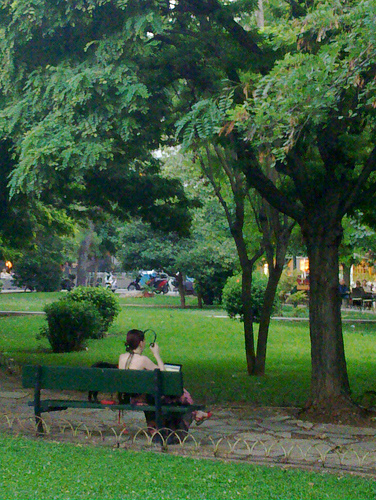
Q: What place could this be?
A: It is a park.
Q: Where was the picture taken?
A: It was taken at the park.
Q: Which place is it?
A: It is a park.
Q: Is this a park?
A: Yes, it is a park.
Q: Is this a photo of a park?
A: Yes, it is showing a park.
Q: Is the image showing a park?
A: Yes, it is showing a park.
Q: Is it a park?
A: Yes, it is a park.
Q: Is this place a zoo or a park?
A: It is a park.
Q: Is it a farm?
A: No, it is a park.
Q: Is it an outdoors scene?
A: Yes, it is outdoors.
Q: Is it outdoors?
A: Yes, it is outdoors.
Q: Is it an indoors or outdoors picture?
A: It is outdoors.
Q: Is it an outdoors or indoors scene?
A: It is outdoors.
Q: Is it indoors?
A: No, it is outdoors.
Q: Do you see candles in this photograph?
A: No, there are no candles.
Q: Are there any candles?
A: No, there are no candles.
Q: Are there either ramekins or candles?
A: No, there are no candles or ramekins.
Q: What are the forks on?
A: The forks are on the tree.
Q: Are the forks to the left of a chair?
A: Yes, the forks are to the left of a chair.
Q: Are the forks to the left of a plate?
A: No, the forks are to the left of a chair.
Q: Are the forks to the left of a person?
A: Yes, the forks are to the left of a person.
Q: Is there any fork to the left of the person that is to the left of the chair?
A: Yes, there are forks to the left of the person.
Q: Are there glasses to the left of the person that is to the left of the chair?
A: No, there are forks to the left of the person.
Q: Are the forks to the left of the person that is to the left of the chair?
A: Yes, the forks are to the left of the person.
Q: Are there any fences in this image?
A: Yes, there is a fence.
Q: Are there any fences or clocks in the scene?
A: Yes, there is a fence.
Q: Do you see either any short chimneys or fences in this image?
A: Yes, there is a short fence.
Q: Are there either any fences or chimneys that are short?
A: Yes, the fence is short.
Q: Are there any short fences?
A: Yes, there is a short fence.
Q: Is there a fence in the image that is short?
A: Yes, there is a fence that is short.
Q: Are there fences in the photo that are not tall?
A: Yes, there is a short fence.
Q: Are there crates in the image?
A: No, there are no crates.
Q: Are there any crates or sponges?
A: No, there are no crates or sponges.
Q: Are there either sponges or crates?
A: No, there are no crates or sponges.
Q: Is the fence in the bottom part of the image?
A: Yes, the fence is in the bottom of the image.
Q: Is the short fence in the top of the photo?
A: No, the fence is in the bottom of the image.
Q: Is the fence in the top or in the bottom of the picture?
A: The fence is in the bottom of the image.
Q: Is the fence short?
A: Yes, the fence is short.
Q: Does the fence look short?
A: Yes, the fence is short.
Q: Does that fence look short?
A: Yes, the fence is short.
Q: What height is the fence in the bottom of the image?
A: The fence is short.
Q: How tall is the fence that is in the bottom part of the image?
A: The fence is short.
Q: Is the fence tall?
A: No, the fence is short.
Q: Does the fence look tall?
A: No, the fence is short.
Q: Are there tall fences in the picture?
A: No, there is a fence but it is short.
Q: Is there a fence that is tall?
A: No, there is a fence but it is short.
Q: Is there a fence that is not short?
A: No, there is a fence but it is short.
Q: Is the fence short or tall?
A: The fence is short.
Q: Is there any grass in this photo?
A: Yes, there is grass.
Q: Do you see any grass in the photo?
A: Yes, there is grass.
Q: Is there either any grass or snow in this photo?
A: Yes, there is grass.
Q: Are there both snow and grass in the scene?
A: No, there is grass but no snow.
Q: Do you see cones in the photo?
A: No, there are no cones.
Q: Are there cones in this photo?
A: No, there are no cones.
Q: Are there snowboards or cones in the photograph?
A: No, there are no cones or snowboards.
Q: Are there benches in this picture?
A: Yes, there is a bench.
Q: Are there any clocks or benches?
A: Yes, there is a bench.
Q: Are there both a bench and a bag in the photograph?
A: No, there is a bench but no bags.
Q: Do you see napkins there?
A: No, there are no napkins.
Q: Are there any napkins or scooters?
A: No, there are no napkins or scooters.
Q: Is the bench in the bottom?
A: Yes, the bench is in the bottom of the image.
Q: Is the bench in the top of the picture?
A: No, the bench is in the bottom of the image.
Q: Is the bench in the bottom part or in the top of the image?
A: The bench is in the bottom of the image.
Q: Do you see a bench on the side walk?
A: Yes, there is a bench on the side walk.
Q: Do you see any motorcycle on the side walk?
A: No, there is a bench on the side walk.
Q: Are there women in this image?
A: Yes, there is a woman.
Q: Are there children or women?
A: Yes, there is a woman.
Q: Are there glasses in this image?
A: No, there are no glasses.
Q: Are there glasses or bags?
A: No, there are no glasses or bags.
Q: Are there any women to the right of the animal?
A: Yes, there is a woman to the right of the animal.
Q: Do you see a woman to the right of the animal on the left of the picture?
A: Yes, there is a woman to the right of the animal.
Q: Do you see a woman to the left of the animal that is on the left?
A: No, the woman is to the right of the animal.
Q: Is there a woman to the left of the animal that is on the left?
A: No, the woman is to the right of the animal.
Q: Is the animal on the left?
A: Yes, the animal is on the left of the image.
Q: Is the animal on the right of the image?
A: No, the animal is on the left of the image.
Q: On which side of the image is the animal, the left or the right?
A: The animal is on the left of the image.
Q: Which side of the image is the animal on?
A: The animal is on the left of the image.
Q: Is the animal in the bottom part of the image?
A: Yes, the animal is in the bottom of the image.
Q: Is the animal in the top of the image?
A: No, the animal is in the bottom of the image.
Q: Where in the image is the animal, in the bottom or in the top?
A: The animal is in the bottom of the image.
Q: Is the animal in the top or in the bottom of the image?
A: The animal is in the bottom of the image.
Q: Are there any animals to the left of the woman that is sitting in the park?
A: Yes, there is an animal to the left of the woman.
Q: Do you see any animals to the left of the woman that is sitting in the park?
A: Yes, there is an animal to the left of the woman.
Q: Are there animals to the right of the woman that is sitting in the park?
A: No, the animal is to the left of the woman.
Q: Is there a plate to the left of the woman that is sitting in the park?
A: No, there is an animal to the left of the woman.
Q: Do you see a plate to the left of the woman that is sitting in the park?
A: No, there is an animal to the left of the woman.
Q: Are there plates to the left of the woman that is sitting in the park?
A: No, there is an animal to the left of the woman.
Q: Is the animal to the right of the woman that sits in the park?
A: No, the animal is to the left of the woman.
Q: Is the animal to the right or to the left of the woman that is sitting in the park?
A: The animal is to the left of the woman.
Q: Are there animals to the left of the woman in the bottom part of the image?
A: Yes, there is an animal to the left of the woman.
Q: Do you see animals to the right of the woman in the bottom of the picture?
A: No, the animal is to the left of the woman.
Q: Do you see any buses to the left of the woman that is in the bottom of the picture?
A: No, there is an animal to the left of the woman.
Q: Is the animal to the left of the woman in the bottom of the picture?
A: Yes, the animal is to the left of the woman.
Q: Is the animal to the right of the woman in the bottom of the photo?
A: No, the animal is to the left of the woman.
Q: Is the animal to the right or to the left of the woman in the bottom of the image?
A: The animal is to the left of the woman.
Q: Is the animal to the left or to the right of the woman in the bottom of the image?
A: The animal is to the left of the woman.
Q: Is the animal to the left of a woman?
A: Yes, the animal is to the left of a woman.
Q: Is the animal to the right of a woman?
A: No, the animal is to the left of a woman.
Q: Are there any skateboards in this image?
A: No, there are no skateboards.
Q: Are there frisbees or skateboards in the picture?
A: No, there are no skateboards or frisbees.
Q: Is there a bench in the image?
A: Yes, there is a bench.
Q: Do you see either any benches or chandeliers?
A: Yes, there is a bench.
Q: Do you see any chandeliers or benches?
A: Yes, there is a bench.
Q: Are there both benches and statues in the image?
A: No, there is a bench but no statues.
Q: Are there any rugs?
A: No, there are no rugs.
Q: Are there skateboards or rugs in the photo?
A: No, there are no rugs or skateboards.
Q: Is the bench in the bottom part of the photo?
A: Yes, the bench is in the bottom of the image.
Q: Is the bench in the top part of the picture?
A: No, the bench is in the bottom of the image.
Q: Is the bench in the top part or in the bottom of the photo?
A: The bench is in the bottom of the image.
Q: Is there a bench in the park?
A: Yes, there is a bench in the park.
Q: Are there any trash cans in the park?
A: No, there is a bench in the park.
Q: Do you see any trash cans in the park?
A: No, there is a bench in the park.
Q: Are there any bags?
A: No, there are no bags.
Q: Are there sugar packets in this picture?
A: No, there are no sugar packets.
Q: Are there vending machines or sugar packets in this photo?
A: No, there are no sugar packets or vending machines.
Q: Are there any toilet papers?
A: No, there are no toilet papers.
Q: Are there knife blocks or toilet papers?
A: No, there are no toilet papers or knife blocks.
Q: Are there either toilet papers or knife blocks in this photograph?
A: No, there are no toilet papers or knife blocks.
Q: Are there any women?
A: Yes, there is a woman.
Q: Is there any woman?
A: Yes, there is a woman.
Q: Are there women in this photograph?
A: Yes, there is a woman.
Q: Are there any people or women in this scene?
A: Yes, there is a woman.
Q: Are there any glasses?
A: No, there are no glasses.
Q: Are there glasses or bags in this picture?
A: No, there are no glasses or bags.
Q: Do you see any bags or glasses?
A: No, there are no glasses or bags.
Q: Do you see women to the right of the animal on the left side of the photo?
A: Yes, there is a woman to the right of the animal.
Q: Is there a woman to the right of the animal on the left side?
A: Yes, there is a woman to the right of the animal.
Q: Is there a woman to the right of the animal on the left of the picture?
A: Yes, there is a woman to the right of the animal.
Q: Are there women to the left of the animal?
A: No, the woman is to the right of the animal.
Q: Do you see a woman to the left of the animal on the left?
A: No, the woman is to the right of the animal.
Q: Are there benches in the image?
A: Yes, there is a bench.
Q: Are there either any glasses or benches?
A: Yes, there is a bench.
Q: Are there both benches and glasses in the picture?
A: No, there is a bench but no glasses.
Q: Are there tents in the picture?
A: No, there are no tents.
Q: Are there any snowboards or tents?
A: No, there are no tents or snowboards.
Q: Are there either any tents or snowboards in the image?
A: No, there are no tents or snowboards.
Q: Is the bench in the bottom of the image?
A: Yes, the bench is in the bottom of the image.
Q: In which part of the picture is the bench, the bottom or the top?
A: The bench is in the bottom of the image.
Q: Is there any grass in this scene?
A: Yes, there is grass.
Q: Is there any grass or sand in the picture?
A: Yes, there is grass.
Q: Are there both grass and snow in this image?
A: No, there is grass but no snow.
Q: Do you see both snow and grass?
A: No, there is grass but no snow.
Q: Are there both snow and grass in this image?
A: No, there is grass but no snow.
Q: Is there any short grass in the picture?
A: Yes, there is short grass.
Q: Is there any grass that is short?
A: Yes, there is grass that is short.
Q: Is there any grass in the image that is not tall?
A: Yes, there is short grass.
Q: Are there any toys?
A: No, there are no toys.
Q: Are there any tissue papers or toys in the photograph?
A: No, there are no toys or tissue papers.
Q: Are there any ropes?
A: No, there are no ropes.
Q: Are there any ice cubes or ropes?
A: No, there are no ropes or ice cubes.